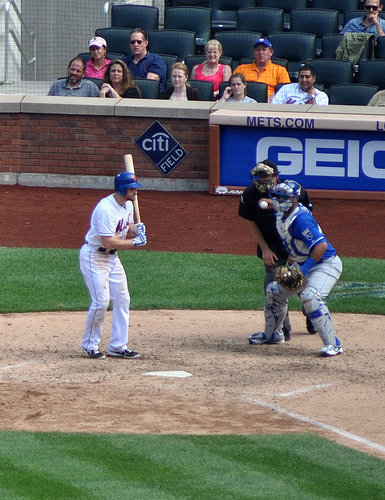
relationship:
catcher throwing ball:
[247, 178, 343, 356] [259, 200, 268, 209]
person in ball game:
[70, 168, 152, 362] [3, 107, 382, 499]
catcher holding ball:
[247, 178, 343, 356] [259, 199, 268, 211]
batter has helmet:
[77, 170, 147, 360] [112, 173, 140, 195]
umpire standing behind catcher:
[237, 161, 316, 338] [247, 178, 343, 356]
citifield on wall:
[140, 132, 184, 177] [2, 94, 381, 262]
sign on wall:
[134, 118, 188, 174] [2, 94, 381, 262]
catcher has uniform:
[247, 178, 343, 356] [261, 206, 342, 349]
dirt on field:
[0, 305, 382, 460] [3, 243, 381, 499]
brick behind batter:
[2, 114, 209, 179] [77, 170, 147, 360]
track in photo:
[1, 309, 383, 465] [3, 2, 383, 498]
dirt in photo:
[0, 305, 382, 460] [3, 2, 383, 498]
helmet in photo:
[269, 178, 300, 212] [3, 2, 383, 498]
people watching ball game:
[48, 2, 381, 111] [3, 107, 382, 499]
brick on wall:
[2, 114, 209, 179] [2, 94, 381, 262]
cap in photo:
[252, 38, 275, 48] [3, 2, 383, 498]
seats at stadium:
[68, 2, 382, 106] [2, 4, 381, 106]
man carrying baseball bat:
[75, 172, 147, 361] [122, 152, 147, 245]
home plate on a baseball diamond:
[140, 370, 196, 379] [3, 339, 356, 404]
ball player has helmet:
[78, 169, 149, 365] [112, 169, 140, 196]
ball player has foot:
[78, 169, 149, 365] [79, 343, 106, 358]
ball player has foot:
[78, 169, 149, 365] [105, 342, 138, 361]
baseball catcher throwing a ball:
[246, 179, 346, 360] [257, 201, 273, 211]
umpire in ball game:
[237, 161, 316, 338] [3, 107, 382, 499]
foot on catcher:
[318, 341, 346, 359] [244, 178, 349, 364]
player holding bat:
[75, 171, 147, 364] [121, 152, 150, 242]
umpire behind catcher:
[237, 161, 316, 338] [244, 178, 349, 364]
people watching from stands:
[48, 2, 381, 111] [40, 3, 383, 115]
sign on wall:
[134, 118, 188, 174] [5, 91, 383, 200]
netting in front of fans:
[1, 2, 383, 117] [47, 24, 331, 112]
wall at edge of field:
[5, 91, 383, 200] [3, 186, 379, 499]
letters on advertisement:
[253, 130, 302, 181] [215, 119, 383, 194]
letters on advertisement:
[301, 134, 345, 178] [215, 119, 383, 194]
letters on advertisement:
[345, 136, 360, 179] [215, 119, 383, 194]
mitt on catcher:
[274, 261, 307, 291] [244, 178, 349, 364]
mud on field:
[3, 377, 311, 436] [3, 243, 381, 499]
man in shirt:
[233, 36, 289, 101] [234, 63, 288, 102]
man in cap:
[233, 36, 289, 101] [253, 36, 271, 47]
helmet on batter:
[115, 171, 138, 195] [72, 159, 151, 357]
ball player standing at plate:
[78, 169, 149, 365] [144, 368, 190, 378]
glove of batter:
[132, 234, 146, 244] [77, 170, 147, 360]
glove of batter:
[133, 222, 145, 233] [77, 170, 147, 360]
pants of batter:
[79, 244, 129, 349] [77, 170, 147, 360]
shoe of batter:
[82, 346, 107, 359] [77, 170, 147, 360]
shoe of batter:
[106, 340, 146, 368] [96, 157, 157, 214]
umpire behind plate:
[237, 161, 316, 338] [143, 367, 193, 378]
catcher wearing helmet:
[247, 178, 343, 356] [270, 181, 300, 216]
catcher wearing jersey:
[247, 178, 343, 356] [287, 214, 337, 260]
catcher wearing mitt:
[247, 178, 343, 356] [273, 264, 305, 290]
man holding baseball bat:
[75, 172, 147, 361] [122, 152, 147, 245]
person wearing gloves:
[70, 168, 152, 362] [129, 221, 149, 251]